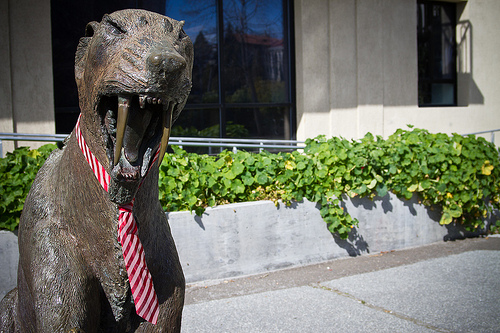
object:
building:
[1, 1, 499, 302]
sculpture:
[0, 9, 196, 332]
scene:
[0, 0, 499, 332]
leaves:
[439, 213, 454, 225]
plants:
[0, 123, 499, 239]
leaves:
[295, 161, 307, 171]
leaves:
[257, 174, 269, 186]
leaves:
[193, 206, 207, 216]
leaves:
[9, 164, 22, 175]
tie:
[76, 112, 161, 324]